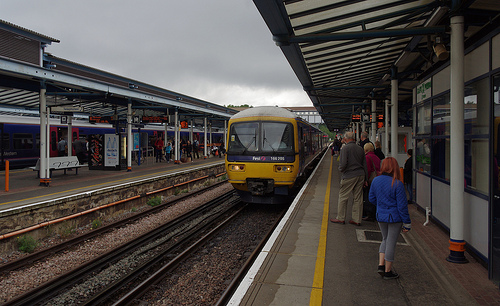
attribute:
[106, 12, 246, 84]
sky — blue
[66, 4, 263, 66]
sky — cloudy, grey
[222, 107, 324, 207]
train — yellow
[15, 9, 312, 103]
sky — blue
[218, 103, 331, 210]
train — yellow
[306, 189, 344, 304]
line — painted, yellow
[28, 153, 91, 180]
bench — wood, white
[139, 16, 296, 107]
sky — blue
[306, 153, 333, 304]
line — yellow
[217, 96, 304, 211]
train — yellow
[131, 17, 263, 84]
clouds — white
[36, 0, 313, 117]
sky — blue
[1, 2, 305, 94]
cloud — white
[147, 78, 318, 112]
cloud — white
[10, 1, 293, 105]
sky — cloudy, grey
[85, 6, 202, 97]
sky — blue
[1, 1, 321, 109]
sky — blue, grey, cloudy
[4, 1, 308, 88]
clouds — white 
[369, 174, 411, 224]
coat — blue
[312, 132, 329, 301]
line — painted, yellow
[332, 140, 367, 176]
sweater — grey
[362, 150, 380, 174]
jacket — red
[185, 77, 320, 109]
cloud — white